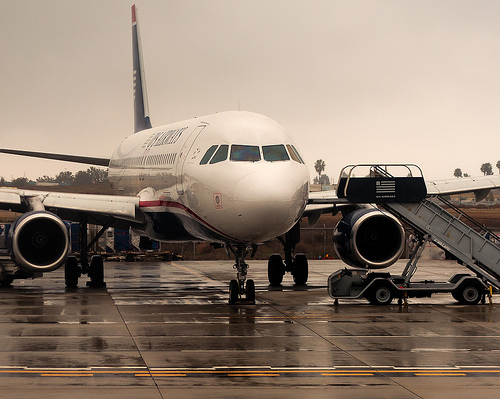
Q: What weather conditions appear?
A: It is cloudy.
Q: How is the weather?
A: It is cloudy.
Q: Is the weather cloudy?
A: Yes, it is cloudy.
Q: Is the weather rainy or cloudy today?
A: It is cloudy.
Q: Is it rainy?
A: No, it is cloudy.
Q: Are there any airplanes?
A: Yes, there is an airplane.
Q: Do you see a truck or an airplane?
A: Yes, there is an airplane.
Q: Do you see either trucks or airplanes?
A: Yes, there is an airplane.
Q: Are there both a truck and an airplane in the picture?
A: No, there is an airplane but no trucks.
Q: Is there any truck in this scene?
A: No, there are no trucks.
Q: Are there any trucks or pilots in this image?
A: No, there are no trucks or pilots.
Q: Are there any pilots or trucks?
A: No, there are no trucks or pilots.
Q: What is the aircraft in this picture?
A: The aircraft is an airplane.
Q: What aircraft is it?
A: The aircraft is an airplane.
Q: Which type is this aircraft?
A: That is an airplane.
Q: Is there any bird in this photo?
A: No, there are no birds.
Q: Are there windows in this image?
A: Yes, there is a window.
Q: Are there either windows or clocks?
A: Yes, there is a window.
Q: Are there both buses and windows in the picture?
A: No, there is a window but no buses.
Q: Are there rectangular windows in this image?
A: Yes, there is a rectangular window.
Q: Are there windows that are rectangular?
A: Yes, there is a window that is rectangular.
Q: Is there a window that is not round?
A: Yes, there is a rectangular window.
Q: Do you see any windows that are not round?
A: Yes, there is a rectangular window.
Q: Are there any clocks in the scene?
A: No, there are no clocks.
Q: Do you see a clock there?
A: No, there are no clocks.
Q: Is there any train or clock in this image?
A: No, there are no clocks or trains.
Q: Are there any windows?
A: Yes, there is a window.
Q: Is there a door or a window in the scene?
A: Yes, there is a window.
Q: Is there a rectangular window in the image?
A: Yes, there is a rectangular window.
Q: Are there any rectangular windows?
A: Yes, there is a rectangular window.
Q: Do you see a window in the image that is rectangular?
A: Yes, there is a window that is rectangular.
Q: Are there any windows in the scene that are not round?
A: Yes, there is a rectangular window.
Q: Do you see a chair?
A: No, there are no chairs.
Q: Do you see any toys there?
A: No, there are no toys.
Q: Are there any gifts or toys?
A: No, there are no toys or gifts.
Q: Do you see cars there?
A: No, there are no cars.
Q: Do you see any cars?
A: No, there are no cars.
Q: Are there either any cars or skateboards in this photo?
A: No, there are no cars or skateboards.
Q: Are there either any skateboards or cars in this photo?
A: No, there are no cars or skateboards.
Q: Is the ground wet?
A: Yes, the ground is wet.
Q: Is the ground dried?
A: No, the ground is wet.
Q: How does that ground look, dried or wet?
A: The ground is wet.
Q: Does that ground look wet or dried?
A: The ground is wet.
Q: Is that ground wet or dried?
A: The ground is wet.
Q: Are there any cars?
A: No, there are no cars.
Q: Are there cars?
A: No, there are no cars.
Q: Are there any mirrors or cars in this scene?
A: No, there are no cars or mirrors.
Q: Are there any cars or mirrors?
A: No, there are no cars or mirrors.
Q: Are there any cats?
A: No, there are no cats.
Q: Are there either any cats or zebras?
A: No, there are no cats or zebras.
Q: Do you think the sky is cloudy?
A: Yes, the sky is cloudy.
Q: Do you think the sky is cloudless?
A: No, the sky is cloudy.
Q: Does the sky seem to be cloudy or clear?
A: The sky is cloudy.